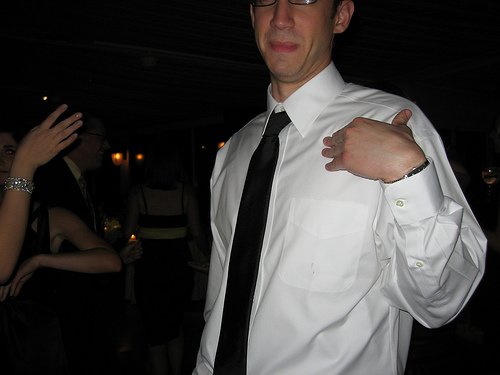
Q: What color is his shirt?
A: White.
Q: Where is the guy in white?
A: In the front.